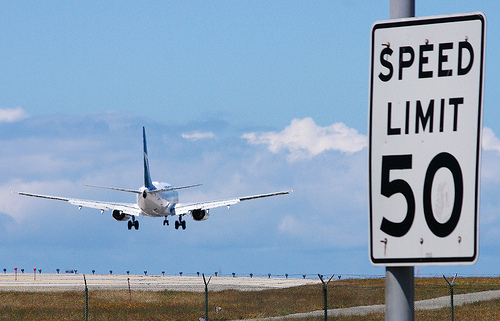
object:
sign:
[367, 13, 485, 264]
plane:
[19, 126, 293, 231]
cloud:
[240, 116, 380, 159]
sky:
[3, 2, 500, 281]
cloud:
[481, 125, 500, 150]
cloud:
[1, 106, 60, 133]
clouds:
[151, 117, 368, 252]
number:
[379, 153, 464, 238]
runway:
[1, 275, 327, 291]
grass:
[3, 275, 500, 321]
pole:
[386, 266, 415, 320]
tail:
[142, 125, 153, 189]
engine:
[192, 208, 209, 222]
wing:
[176, 191, 294, 218]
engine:
[112, 211, 130, 221]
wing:
[12, 190, 139, 216]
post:
[84, 276, 89, 321]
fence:
[0, 267, 500, 321]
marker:
[9, 265, 21, 281]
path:
[275, 283, 499, 317]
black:
[439, 18, 478, 21]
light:
[34, 267, 38, 281]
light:
[56, 268, 61, 276]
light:
[110, 269, 114, 275]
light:
[144, 269, 147, 277]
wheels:
[128, 219, 139, 231]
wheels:
[175, 219, 186, 230]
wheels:
[162, 219, 169, 225]